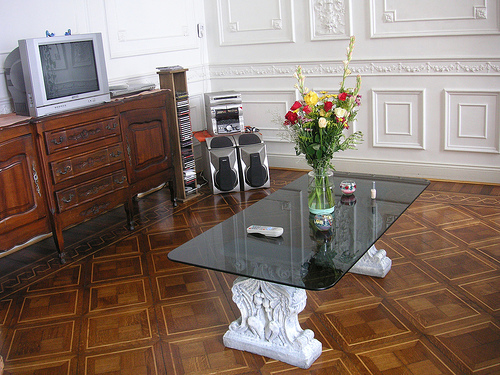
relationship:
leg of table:
[221, 274, 325, 366] [159, 159, 437, 295]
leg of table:
[318, 201, 388, 274] [159, 159, 437, 295]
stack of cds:
[171, 87, 200, 195] [178, 137, 194, 142]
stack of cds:
[171, 87, 200, 195] [177, 109, 192, 113]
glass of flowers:
[166, 172, 432, 292] [268, 33, 368, 175]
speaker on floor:
[201, 132, 242, 196] [0, 165, 493, 372]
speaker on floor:
[235, 130, 270, 192] [0, 165, 493, 372]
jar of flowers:
[286, 89, 359, 239] [274, 75, 351, 171]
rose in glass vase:
[320, 99, 333, 112] [306, 167, 335, 216]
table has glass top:
[164, 163, 436, 370] [170, 172, 430, 291]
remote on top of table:
[246, 221, 291, 246] [163, 171, 441, 301]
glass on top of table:
[166, 172, 432, 292] [148, 156, 452, 293]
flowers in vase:
[336, 108, 348, 119] [308, 173, 338, 231]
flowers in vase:
[284, 110, 299, 122] [308, 173, 338, 231]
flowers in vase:
[334, 95, 346, 103] [308, 173, 338, 231]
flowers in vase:
[302, 92, 317, 104] [308, 173, 338, 231]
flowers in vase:
[285, 98, 307, 112] [308, 173, 338, 231]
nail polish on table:
[371, 180, 377, 198] [167, 168, 430, 289]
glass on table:
[166, 172, 432, 292] [164, 163, 436, 370]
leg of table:
[219, 235, 323, 371] [164, 168, 434, 372]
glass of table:
[281, 162, 426, 284] [169, 130, 461, 372]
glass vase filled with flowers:
[300, 161, 338, 213] [284, 82, 360, 172]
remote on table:
[246, 224, 284, 237] [173, 168, 430, 362]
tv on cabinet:
[25, 30, 123, 108] [21, 120, 178, 238]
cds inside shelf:
[173, 92, 200, 198] [154, 62, 204, 205]